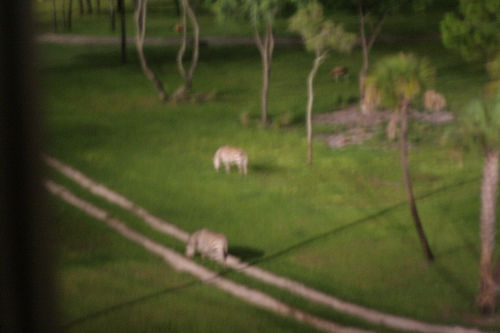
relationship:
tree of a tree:
[224, 4, 291, 127] [218, 4, 296, 127]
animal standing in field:
[207, 140, 255, 184] [146, 105, 333, 211]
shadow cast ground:
[230, 241, 269, 265] [230, 231, 282, 259]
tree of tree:
[224, 4, 291, 127] [218, 4, 296, 127]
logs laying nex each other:
[387, 107, 399, 143] [357, 90, 396, 137]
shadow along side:
[230, 241, 269, 265] [227, 207, 310, 259]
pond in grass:
[284, 91, 471, 149] [29, 52, 468, 326]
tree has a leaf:
[366, 44, 450, 267] [356, 43, 443, 125]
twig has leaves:
[249, 9, 262, 38] [215, 3, 261, 31]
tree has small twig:
[218, 4, 296, 127] [250, 1, 261, 27]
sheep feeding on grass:
[207, 140, 255, 184] [29, 52, 468, 326]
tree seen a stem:
[218, 4, 296, 127] [253, 20, 277, 124]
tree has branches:
[288, 3, 357, 168] [323, 30, 338, 58]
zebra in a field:
[207, 140, 255, 184] [146, 105, 333, 211]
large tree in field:
[474, 146, 495, 277] [7, 2, 495, 327]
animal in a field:
[209, 147, 255, 176] [7, 2, 495, 327]